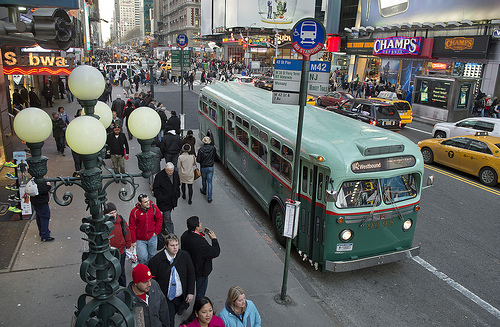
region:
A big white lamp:
[61, 115, 110, 156]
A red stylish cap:
[129, 260, 159, 280]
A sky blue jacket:
[225, 308, 272, 325]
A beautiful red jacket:
[133, 211, 168, 234]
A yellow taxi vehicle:
[423, 143, 499, 173]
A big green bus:
[315, 135, 425, 272]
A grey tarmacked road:
[346, 283, 450, 325]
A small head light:
[338, 229, 356, 239]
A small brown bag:
[193, 168, 200, 178]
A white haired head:
[165, 160, 176, 175]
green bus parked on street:
[188, 72, 443, 268]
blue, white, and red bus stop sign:
[286, 18, 330, 55]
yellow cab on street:
[408, 123, 499, 174]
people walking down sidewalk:
[80, 48, 256, 325]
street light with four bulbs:
[6, 55, 181, 320]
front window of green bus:
[335, 175, 419, 204]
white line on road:
[411, 248, 488, 324]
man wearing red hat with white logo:
[117, 260, 174, 315]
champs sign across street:
[368, 29, 425, 55]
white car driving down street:
[432, 104, 499, 145]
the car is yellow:
[406, 108, 497, 181]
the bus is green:
[190, 65, 461, 302]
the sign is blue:
[275, 16, 330, 60]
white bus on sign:
[293, 20, 320, 47]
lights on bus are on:
[315, 200, 427, 251]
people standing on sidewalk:
[99, 125, 289, 320]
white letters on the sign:
[363, 30, 433, 58]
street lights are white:
[12, 48, 161, 165]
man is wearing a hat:
[127, 262, 180, 310]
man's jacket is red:
[133, 200, 170, 248]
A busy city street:
[32, 13, 497, 318]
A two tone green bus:
[195, 70, 430, 272]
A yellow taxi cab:
[417, 115, 498, 180]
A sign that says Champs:
[369, 31, 422, 59]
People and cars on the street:
[94, 31, 226, 97]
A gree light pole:
[8, 47, 179, 248]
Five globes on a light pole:
[5, 44, 173, 166]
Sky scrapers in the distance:
[102, 5, 174, 55]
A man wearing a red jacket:
[126, 192, 162, 244]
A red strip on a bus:
[193, 91, 313, 218]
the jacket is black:
[123, 204, 173, 245]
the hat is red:
[126, 261, 159, 281]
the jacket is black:
[154, 167, 184, 209]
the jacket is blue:
[218, 299, 273, 325]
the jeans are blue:
[202, 168, 217, 202]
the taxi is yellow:
[428, 126, 498, 194]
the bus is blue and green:
[208, 83, 434, 283]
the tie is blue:
[169, 266, 177, 298]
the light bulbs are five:
[15, 74, 175, 176]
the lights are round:
[333, 228, 362, 247]